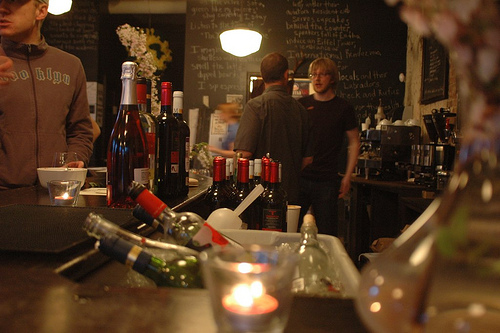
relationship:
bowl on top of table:
[34, 162, 88, 191] [5, 159, 215, 263]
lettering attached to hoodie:
[2, 62, 73, 87] [0, 35, 97, 193]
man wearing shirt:
[296, 60, 368, 247] [283, 88, 354, 198]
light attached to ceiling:
[210, 14, 264, 72] [140, 1, 388, 16]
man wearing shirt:
[296, 60, 368, 247] [286, 83, 349, 177]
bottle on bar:
[110, 63, 154, 227] [8, 162, 368, 325]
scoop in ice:
[207, 179, 267, 239] [197, 212, 341, 301]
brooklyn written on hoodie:
[4, 61, 83, 98] [0, 35, 97, 193]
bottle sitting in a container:
[89, 217, 208, 298] [146, 215, 376, 301]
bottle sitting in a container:
[132, 182, 239, 260] [146, 215, 376, 301]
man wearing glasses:
[296, 60, 368, 247] [305, 67, 332, 78]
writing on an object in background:
[172, 84, 442, 187] [132, 99, 468, 196]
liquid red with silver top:
[100, 156, 151, 208] [100, 100, 174, 143]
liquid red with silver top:
[100, 156, 151, 208] [116, 100, 126, 113]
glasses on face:
[305, 68, 330, 81] [305, 49, 330, 94]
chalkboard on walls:
[285, 7, 356, 38] [308, 13, 376, 52]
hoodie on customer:
[0, 35, 97, 193] [2, 1, 98, 190]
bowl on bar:
[34, 162, 88, 191] [1, 151, 269, 327]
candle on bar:
[226, 277, 278, 331] [8, 162, 368, 325]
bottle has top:
[110, 63, 154, 208] [114, 55, 144, 103]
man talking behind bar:
[296, 60, 368, 247] [2, 159, 481, 325]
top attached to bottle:
[80, 236, 150, 266] [94, 228, 208, 284]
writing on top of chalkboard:
[195, 45, 237, 85] [185, 35, 247, 115]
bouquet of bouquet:
[111, 21, 173, 114] [111, 21, 173, 114]